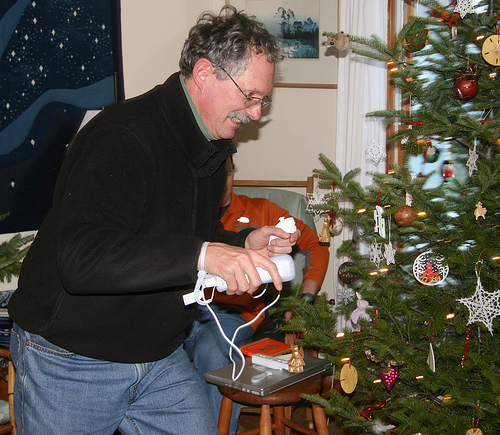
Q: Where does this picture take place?
A: Inside of a home.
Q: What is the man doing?
A: Playing a video game.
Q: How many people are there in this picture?
A: Two.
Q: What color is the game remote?
A: White.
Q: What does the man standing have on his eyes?
A: Glasses.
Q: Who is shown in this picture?
A: Men.